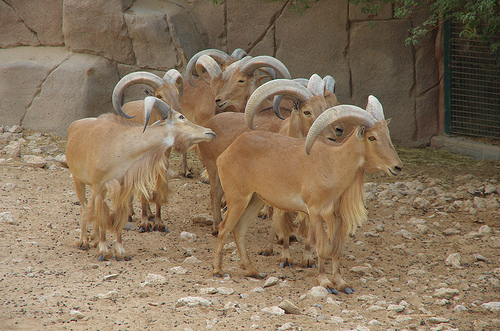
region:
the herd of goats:
[65, 46, 402, 296]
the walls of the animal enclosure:
[0, 0, 499, 160]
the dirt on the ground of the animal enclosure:
[0, 124, 498, 329]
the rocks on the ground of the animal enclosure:
[0, 123, 497, 329]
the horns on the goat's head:
[305, 93, 384, 155]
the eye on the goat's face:
[366, 135, 376, 141]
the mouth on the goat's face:
[385, 165, 397, 175]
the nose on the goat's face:
[393, 163, 403, 171]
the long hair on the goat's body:
[321, 165, 369, 241]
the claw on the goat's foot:
[330, 287, 340, 294]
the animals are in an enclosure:
[10, 6, 499, 320]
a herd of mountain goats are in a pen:
[61, 39, 404, 296]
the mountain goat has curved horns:
[296, 90, 388, 160]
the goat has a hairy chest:
[329, 155, 383, 262]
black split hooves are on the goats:
[75, 210, 361, 299]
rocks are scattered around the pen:
[6, 121, 496, 328]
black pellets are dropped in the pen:
[11, 150, 493, 329]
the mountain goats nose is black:
[388, 158, 407, 177]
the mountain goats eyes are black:
[295, 99, 392, 150]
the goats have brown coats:
[64, 57, 396, 291]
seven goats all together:
[63, 51, 408, 300]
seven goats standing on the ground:
[61, 45, 410, 300]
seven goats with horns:
[51, 42, 413, 297]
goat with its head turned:
[63, 95, 203, 260]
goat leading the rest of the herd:
[197, 95, 406, 297]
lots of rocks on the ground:
[381, 190, 487, 329]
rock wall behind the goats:
[0, 0, 109, 110]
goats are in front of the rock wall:
[45, 0, 407, 300]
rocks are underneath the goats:
[63, 42, 403, 297]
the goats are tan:
[58, 40, 403, 297]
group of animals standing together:
[54, 28, 398, 275]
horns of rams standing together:
[295, 89, 382, 149]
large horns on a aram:
[237, 60, 334, 120]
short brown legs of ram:
[206, 197, 351, 297]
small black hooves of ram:
[97, 252, 132, 271]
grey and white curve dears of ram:
[135, 93, 168, 133]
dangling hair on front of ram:
[126, 158, 168, 206]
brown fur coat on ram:
[86, 129, 154, 203]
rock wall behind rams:
[9, 10, 135, 111]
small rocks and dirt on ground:
[402, 174, 477, 314]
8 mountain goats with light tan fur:
[30, 30, 416, 292]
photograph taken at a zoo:
[19, 10, 462, 305]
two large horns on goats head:
[300, 94, 400, 152]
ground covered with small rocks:
[37, 172, 494, 321]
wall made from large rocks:
[12, 0, 447, 126]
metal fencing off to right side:
[435, 3, 499, 132]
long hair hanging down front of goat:
[90, 146, 178, 226]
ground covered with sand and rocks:
[17, 190, 482, 312]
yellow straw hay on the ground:
[400, 143, 472, 173]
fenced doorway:
[437, 5, 498, 150]